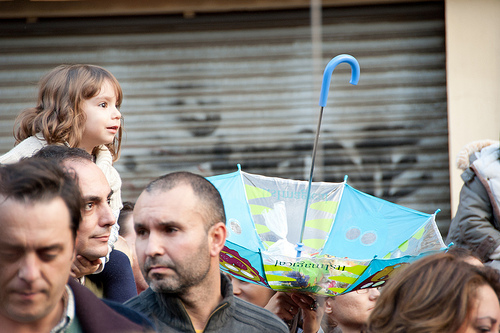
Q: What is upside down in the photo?
A: Umbrella.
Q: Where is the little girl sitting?
A: Shoulders.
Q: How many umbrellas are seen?
A: One.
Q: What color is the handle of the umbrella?
A: Blue.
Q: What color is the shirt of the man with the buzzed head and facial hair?
A: Grey.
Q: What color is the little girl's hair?
A: Brown.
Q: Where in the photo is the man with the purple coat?
A: Bottom left.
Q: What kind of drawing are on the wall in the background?
A: Graffiti.